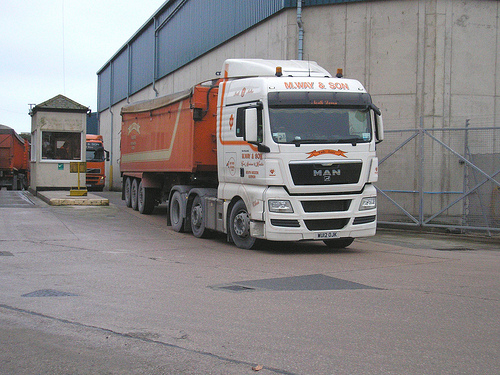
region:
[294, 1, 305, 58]
blue rain gutter on the building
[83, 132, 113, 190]
orange truck by the guard tower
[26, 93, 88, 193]
guard tower with a window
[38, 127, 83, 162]
window on the guard tower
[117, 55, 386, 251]
orange and white truck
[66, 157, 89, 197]
yellow sign by the guard tower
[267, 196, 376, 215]
headlights on the truck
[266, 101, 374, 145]
windshield on the white and orange truck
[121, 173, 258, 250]
wheels on the truck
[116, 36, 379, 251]
12 wheeler truck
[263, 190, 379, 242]
two headlights of a truck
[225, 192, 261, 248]
front tire on truck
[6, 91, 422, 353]
pavement truck is parked on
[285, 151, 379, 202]
front grill of white truck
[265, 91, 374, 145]
front windshield of truck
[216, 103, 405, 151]
front mirrors on white truck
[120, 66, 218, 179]
orange container on truck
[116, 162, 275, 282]
lots of tires on trucks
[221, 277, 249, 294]
a vent on the ground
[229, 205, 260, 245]
the front wheel of a truck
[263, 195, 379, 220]
the head lights of a truck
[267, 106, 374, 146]
the windshield of a truck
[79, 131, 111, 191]
an orange truck behind the white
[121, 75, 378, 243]
a white truck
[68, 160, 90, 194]
a yellow sign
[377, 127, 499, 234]
a silver metal gate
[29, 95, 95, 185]
a small shelter by the trucks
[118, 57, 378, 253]
orange and white tractor trailor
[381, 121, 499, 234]
grey metal chain link fence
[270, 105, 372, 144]
wind shield on truck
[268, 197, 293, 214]
head light on truck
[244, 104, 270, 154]
side mirror on truck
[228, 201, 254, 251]
grey tire on truck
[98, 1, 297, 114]
blue siding on building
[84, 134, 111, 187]
orange truck in lot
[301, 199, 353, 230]
black grill on truck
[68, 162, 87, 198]
yellow sign on sidewalk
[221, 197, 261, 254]
front wheels of truck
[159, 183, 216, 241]
center wheels of truck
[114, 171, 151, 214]
back wheels of truck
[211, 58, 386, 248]
front cabin of truck is white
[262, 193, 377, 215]
the headlights of truck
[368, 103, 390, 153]
mirror on right side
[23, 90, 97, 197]
roof of cabin is black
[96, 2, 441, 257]
a truck in front a building